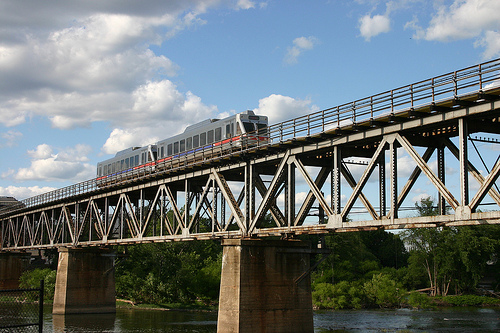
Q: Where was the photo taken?
A: It was taken at the forest.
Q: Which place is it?
A: It is a forest.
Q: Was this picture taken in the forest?
A: Yes, it was taken in the forest.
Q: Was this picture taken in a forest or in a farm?
A: It was taken at a forest.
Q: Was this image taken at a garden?
A: No, the picture was taken in a forest.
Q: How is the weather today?
A: It is cloudy.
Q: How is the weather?
A: It is cloudy.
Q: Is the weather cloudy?
A: Yes, it is cloudy.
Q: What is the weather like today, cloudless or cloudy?
A: It is cloudy.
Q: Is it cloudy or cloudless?
A: It is cloudy.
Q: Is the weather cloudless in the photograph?
A: No, it is cloudy.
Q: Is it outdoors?
A: Yes, it is outdoors.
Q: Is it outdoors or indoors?
A: It is outdoors.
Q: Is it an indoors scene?
A: No, it is outdoors.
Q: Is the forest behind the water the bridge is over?
A: Yes, the forest is behind the water.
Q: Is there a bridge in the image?
A: Yes, there is a bridge.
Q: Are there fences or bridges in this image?
A: Yes, there is a bridge.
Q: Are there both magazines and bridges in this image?
A: No, there is a bridge but no magazines.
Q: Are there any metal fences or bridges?
A: Yes, there is a metal bridge.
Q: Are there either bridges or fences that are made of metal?
A: Yes, the bridge is made of metal.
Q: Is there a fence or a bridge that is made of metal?
A: Yes, the bridge is made of metal.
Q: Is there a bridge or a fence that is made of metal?
A: Yes, the bridge is made of metal.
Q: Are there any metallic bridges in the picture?
A: Yes, there is a metal bridge.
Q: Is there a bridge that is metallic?
A: Yes, there is a bridge that is metallic.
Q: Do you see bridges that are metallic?
A: Yes, there is a bridge that is metallic.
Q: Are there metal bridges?
A: Yes, there is a bridge that is made of metal.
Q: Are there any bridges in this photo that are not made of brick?
A: Yes, there is a bridge that is made of metal.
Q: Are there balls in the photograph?
A: No, there are no balls.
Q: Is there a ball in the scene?
A: No, there are no balls.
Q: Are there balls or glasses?
A: No, there are no balls or glasses.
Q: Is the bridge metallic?
A: Yes, the bridge is metallic.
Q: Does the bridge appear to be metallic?
A: Yes, the bridge is metallic.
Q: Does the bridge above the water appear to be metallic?
A: Yes, the bridge is metallic.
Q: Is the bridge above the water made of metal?
A: Yes, the bridge is made of metal.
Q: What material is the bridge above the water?
A: The bridge is made of metal.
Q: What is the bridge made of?
A: The bridge is made of metal.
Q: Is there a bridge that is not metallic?
A: No, there is a bridge but it is metallic.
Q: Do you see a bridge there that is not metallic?
A: No, there is a bridge but it is metallic.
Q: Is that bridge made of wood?
A: No, the bridge is made of metal.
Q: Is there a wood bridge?
A: No, there is a bridge but it is made of metal.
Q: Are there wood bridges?
A: No, there is a bridge but it is made of metal.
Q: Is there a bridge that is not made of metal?
A: No, there is a bridge but it is made of metal.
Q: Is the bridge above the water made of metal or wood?
A: The bridge is made of metal.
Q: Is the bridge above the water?
A: Yes, the bridge is above the water.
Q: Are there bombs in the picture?
A: No, there are no bombs.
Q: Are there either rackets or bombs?
A: No, there are no bombs or rackets.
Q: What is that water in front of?
A: The water is in front of the forest.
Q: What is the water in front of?
A: The water is in front of the forest.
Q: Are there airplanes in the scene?
A: No, there are no airplanes.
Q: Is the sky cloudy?
A: Yes, the sky is cloudy.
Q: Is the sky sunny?
A: No, the sky is cloudy.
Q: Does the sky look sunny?
A: No, the sky is cloudy.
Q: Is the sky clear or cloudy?
A: The sky is cloudy.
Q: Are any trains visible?
A: Yes, there is a train.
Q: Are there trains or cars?
A: Yes, there is a train.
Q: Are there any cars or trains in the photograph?
A: Yes, there is a train.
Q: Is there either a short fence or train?
A: Yes, there is a short train.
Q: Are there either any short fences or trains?
A: Yes, there is a short train.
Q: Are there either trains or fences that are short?
A: Yes, the train is short.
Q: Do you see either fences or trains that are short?
A: Yes, the train is short.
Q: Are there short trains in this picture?
A: Yes, there is a short train.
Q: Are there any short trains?
A: Yes, there is a short train.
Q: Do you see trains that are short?
A: Yes, there is a train that is short.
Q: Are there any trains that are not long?
A: Yes, there is a short train.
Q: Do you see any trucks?
A: No, there are no trucks.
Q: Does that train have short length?
A: Yes, the train is short.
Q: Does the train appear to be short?
A: Yes, the train is short.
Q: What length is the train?
A: The train is short.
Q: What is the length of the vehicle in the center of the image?
A: The train is short.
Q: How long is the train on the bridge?
A: The train is short.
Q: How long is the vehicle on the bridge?
A: The train is short.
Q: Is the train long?
A: No, the train is short.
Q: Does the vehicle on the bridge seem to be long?
A: No, the train is short.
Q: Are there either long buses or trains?
A: No, there is a train but it is short.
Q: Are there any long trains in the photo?
A: No, there is a train but it is short.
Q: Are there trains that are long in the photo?
A: No, there is a train but it is short.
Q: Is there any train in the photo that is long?
A: No, there is a train but it is short.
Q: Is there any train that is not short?
A: No, there is a train but it is short.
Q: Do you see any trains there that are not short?
A: No, there is a train but it is short.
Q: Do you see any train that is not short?
A: No, there is a train but it is short.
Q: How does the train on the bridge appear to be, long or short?
A: The train is short.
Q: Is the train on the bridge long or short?
A: The train is short.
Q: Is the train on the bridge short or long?
A: The train is short.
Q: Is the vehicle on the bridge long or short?
A: The train is short.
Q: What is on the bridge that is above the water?
A: The train is on the bridge.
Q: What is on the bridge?
A: The train is on the bridge.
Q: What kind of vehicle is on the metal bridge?
A: The vehicle is a train.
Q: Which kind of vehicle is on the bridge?
A: The vehicle is a train.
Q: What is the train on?
A: The train is on the bridge.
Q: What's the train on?
A: The train is on the bridge.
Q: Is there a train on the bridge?
A: Yes, there is a train on the bridge.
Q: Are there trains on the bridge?
A: Yes, there is a train on the bridge.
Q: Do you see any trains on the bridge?
A: Yes, there is a train on the bridge.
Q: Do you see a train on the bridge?
A: Yes, there is a train on the bridge.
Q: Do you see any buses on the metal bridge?
A: No, there is a train on the bridge.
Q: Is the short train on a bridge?
A: Yes, the train is on a bridge.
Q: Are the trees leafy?
A: Yes, the trees are leafy.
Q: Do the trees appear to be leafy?
A: Yes, the trees are leafy.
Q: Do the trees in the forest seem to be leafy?
A: Yes, the trees are leafy.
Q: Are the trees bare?
A: No, the trees are leafy.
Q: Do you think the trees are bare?
A: No, the trees are leafy.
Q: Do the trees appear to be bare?
A: No, the trees are leafy.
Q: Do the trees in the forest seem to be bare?
A: No, the trees are leafy.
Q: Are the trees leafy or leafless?
A: The trees are leafy.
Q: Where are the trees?
A: The trees are in the forest.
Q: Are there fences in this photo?
A: Yes, there is a fence.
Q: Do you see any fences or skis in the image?
A: Yes, there is a fence.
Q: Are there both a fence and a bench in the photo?
A: No, there is a fence but no benches.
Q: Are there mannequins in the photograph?
A: No, there are no mannequins.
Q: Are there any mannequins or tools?
A: No, there are no mannequins or tools.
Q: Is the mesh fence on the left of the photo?
A: Yes, the fence is on the left of the image.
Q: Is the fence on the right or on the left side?
A: The fence is on the left of the image.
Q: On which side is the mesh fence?
A: The fence is on the left of the image.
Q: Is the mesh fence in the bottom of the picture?
A: Yes, the fence is in the bottom of the image.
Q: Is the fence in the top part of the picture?
A: No, the fence is in the bottom of the image.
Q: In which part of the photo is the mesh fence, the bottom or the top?
A: The fence is in the bottom of the image.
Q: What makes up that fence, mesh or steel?
A: The fence is made of mesh.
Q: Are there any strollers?
A: No, there are no strollers.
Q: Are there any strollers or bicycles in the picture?
A: No, there are no strollers or bicycles.